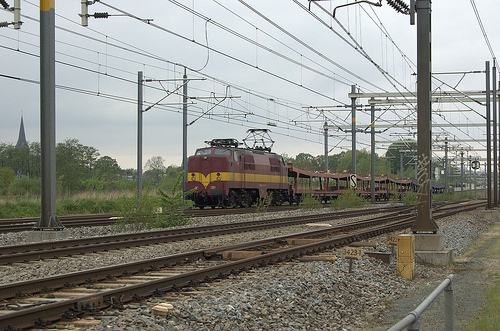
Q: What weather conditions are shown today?
A: It is cloudy.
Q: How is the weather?
A: It is cloudy.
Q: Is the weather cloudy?
A: Yes, it is cloudy.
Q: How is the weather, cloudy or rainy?
A: It is cloudy.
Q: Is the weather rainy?
A: No, it is cloudy.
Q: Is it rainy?
A: No, it is cloudy.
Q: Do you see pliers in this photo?
A: No, there are no pliers.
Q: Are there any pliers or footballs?
A: No, there are no pliers or footballs.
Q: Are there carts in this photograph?
A: No, there are no carts.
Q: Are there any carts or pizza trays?
A: No, there are no carts or pizza trays.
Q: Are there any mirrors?
A: No, there are no mirrors.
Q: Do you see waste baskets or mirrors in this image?
A: No, there are no mirrors or waste baskets.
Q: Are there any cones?
A: No, there are no cones.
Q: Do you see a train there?
A: Yes, there is a train.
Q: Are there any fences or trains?
A: Yes, there is a train.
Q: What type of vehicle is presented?
A: The vehicle is a train.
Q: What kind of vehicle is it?
A: The vehicle is a train.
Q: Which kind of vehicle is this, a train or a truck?
A: That is a train.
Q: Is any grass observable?
A: Yes, there is grass.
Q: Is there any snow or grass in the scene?
A: Yes, there is grass.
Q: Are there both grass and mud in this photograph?
A: No, there is grass but no mud.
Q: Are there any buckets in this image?
A: No, there are no buckets.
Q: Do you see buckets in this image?
A: No, there are no buckets.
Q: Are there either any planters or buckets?
A: No, there are no buckets or planters.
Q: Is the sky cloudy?
A: Yes, the sky is cloudy.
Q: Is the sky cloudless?
A: No, the sky is cloudy.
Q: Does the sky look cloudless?
A: No, the sky is cloudy.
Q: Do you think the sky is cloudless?
A: No, the sky is cloudy.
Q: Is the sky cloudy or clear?
A: The sky is cloudy.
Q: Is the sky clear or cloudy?
A: The sky is cloudy.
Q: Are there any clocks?
A: No, there are no clocks.